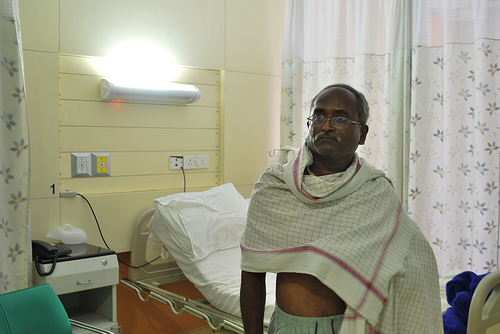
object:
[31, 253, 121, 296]
drawer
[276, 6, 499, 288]
curtain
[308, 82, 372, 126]
grey hair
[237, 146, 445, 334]
sheet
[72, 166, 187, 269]
cord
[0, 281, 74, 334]
chair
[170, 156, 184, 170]
outlets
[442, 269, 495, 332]
shirt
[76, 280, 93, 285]
knob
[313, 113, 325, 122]
open eyes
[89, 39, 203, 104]
light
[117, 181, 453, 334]
bed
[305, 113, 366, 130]
glasses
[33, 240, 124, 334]
stand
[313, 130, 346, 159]
mustache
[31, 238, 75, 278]
phone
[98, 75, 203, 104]
light fixture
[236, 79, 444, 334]
man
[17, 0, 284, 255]
wall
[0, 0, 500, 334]
room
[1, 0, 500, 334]
hospital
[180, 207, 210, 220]
sheets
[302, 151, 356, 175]
neck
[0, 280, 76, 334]
back